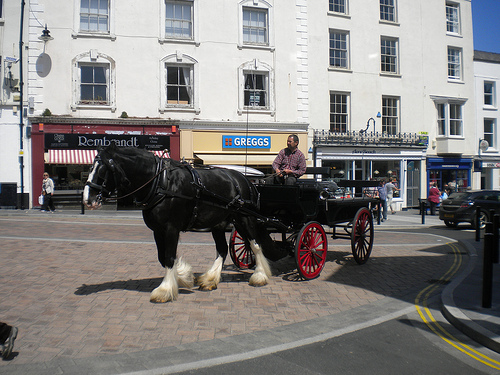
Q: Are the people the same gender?
A: No, they are both male and female.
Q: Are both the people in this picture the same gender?
A: No, they are both male and female.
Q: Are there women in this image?
A: Yes, there is a woman.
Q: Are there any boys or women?
A: Yes, there is a woman.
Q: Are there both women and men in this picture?
A: Yes, there are both a woman and a man.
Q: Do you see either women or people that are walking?
A: Yes, the woman is walking.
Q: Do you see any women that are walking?
A: Yes, there is a woman that is walking.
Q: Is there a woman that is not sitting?
A: Yes, there is a woman that is walking.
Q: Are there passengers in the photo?
A: No, there are no passengers.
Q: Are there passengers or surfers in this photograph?
A: No, there are no passengers or surfers.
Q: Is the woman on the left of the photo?
A: Yes, the woman is on the left of the image.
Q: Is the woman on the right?
A: No, the woman is on the left of the image.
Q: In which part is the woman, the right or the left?
A: The woman is on the left of the image.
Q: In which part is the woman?
A: The woman is on the left of the image.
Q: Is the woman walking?
A: Yes, the woman is walking.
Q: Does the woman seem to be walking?
A: Yes, the woman is walking.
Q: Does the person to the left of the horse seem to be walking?
A: Yes, the woman is walking.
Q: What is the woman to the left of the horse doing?
A: The woman is walking.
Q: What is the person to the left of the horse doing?
A: The woman is walking.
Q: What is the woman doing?
A: The woman is walking.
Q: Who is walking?
A: The woman is walking.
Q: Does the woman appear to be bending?
A: No, the woman is walking.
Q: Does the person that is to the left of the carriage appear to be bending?
A: No, the woman is walking.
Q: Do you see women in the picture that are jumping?
A: No, there is a woman but she is walking.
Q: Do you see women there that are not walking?
A: No, there is a woman but she is walking.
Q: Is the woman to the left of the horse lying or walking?
A: The woman is walking.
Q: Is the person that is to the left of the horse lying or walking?
A: The woman is walking.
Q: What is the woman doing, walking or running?
A: The woman is walking.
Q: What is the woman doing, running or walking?
A: The woman is walking.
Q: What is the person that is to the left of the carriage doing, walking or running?
A: The woman is walking.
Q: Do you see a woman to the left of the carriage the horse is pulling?
A: Yes, there is a woman to the left of the carriage.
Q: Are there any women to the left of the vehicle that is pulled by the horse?
A: Yes, there is a woman to the left of the carriage.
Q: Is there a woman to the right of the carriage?
A: No, the woman is to the left of the carriage.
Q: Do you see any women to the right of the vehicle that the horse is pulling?
A: No, the woman is to the left of the carriage.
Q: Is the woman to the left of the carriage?
A: Yes, the woman is to the left of the carriage.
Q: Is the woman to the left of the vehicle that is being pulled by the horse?
A: Yes, the woman is to the left of the carriage.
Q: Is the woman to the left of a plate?
A: No, the woman is to the left of the carriage.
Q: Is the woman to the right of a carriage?
A: No, the woman is to the left of a carriage.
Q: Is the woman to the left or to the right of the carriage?
A: The woman is to the left of the carriage.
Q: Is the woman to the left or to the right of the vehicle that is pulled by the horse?
A: The woman is to the left of the carriage.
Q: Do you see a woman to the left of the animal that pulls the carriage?
A: Yes, there is a woman to the left of the horse.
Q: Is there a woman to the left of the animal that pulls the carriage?
A: Yes, there is a woman to the left of the horse.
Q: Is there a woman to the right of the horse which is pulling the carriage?
A: No, the woman is to the left of the horse.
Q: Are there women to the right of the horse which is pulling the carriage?
A: No, the woman is to the left of the horse.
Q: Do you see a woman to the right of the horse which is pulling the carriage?
A: No, the woman is to the left of the horse.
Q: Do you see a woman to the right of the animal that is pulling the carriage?
A: No, the woman is to the left of the horse.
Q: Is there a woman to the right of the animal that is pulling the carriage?
A: No, the woman is to the left of the horse.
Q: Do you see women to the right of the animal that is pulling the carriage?
A: No, the woman is to the left of the horse.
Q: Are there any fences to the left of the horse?
A: No, there is a woman to the left of the horse.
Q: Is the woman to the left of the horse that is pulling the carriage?
A: Yes, the woman is to the left of the horse.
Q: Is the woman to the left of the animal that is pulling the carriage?
A: Yes, the woman is to the left of the horse.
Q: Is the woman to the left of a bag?
A: No, the woman is to the left of the horse.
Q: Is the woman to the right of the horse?
A: No, the woman is to the left of the horse.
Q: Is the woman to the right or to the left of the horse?
A: The woman is to the left of the horse.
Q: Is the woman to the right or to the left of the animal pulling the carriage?
A: The woman is to the left of the horse.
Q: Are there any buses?
A: No, there are no buses.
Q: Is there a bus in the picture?
A: No, there are no buses.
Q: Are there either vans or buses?
A: No, there are no buses or vans.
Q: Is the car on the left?
A: No, the car is on the right of the image.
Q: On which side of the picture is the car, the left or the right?
A: The car is on the right of the image.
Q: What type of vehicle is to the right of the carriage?
A: The vehicle is a car.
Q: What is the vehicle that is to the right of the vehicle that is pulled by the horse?
A: The vehicle is a car.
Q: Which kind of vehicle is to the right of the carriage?
A: The vehicle is a car.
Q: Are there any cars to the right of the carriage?
A: Yes, there is a car to the right of the carriage.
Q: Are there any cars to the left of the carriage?
A: No, the car is to the right of the carriage.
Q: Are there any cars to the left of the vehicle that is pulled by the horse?
A: No, the car is to the right of the carriage.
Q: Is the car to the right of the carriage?
A: Yes, the car is to the right of the carriage.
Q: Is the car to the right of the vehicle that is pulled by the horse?
A: Yes, the car is to the right of the carriage.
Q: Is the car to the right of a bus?
A: No, the car is to the right of the carriage.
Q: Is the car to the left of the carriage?
A: No, the car is to the right of the carriage.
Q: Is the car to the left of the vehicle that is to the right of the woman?
A: No, the car is to the right of the carriage.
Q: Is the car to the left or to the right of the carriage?
A: The car is to the right of the carriage.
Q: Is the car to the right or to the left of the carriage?
A: The car is to the right of the carriage.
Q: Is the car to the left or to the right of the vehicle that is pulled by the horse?
A: The car is to the right of the carriage.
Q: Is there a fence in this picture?
A: No, there are no fences.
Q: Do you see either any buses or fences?
A: No, there are no fences or buses.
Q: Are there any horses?
A: Yes, there is a horse.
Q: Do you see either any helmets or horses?
A: Yes, there is a horse.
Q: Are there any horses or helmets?
A: Yes, there is a horse.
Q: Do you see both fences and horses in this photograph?
A: No, there is a horse but no fences.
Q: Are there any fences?
A: No, there are no fences.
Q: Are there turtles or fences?
A: No, there are no fences or turtles.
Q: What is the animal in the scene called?
A: The animal is a horse.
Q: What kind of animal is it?
A: The animal is a horse.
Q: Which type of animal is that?
A: This is a horse.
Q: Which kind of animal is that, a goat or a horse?
A: This is a horse.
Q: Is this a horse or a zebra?
A: This is a horse.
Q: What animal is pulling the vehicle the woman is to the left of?
A: The horse is pulling the carriage.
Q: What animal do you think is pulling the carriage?
A: The animal is a horse.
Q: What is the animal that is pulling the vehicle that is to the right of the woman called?
A: The animal is a horse.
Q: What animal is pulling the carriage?
A: The animal is a horse.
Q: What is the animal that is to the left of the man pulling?
A: The horse is pulling the carriage.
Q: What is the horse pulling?
A: The horse is pulling the carriage.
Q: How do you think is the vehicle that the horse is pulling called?
A: The vehicle is a carriage.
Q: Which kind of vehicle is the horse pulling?
A: The horse is pulling the carriage.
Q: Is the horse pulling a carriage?
A: Yes, the horse is pulling a carriage.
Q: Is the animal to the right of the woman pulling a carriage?
A: Yes, the horse is pulling a carriage.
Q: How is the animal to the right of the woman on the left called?
A: The animal is a horse.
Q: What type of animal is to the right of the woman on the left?
A: The animal is a horse.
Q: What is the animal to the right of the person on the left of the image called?
A: The animal is a horse.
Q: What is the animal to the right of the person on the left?
A: The animal is a horse.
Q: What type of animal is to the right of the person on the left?
A: The animal is a horse.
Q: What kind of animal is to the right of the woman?
A: The animal is a horse.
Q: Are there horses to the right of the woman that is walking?
A: Yes, there is a horse to the right of the woman.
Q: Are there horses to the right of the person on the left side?
A: Yes, there is a horse to the right of the woman.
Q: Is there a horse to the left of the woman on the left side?
A: No, the horse is to the right of the woman.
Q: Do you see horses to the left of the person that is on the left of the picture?
A: No, the horse is to the right of the woman.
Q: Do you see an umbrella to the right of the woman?
A: No, there is a horse to the right of the woman.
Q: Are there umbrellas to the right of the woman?
A: No, there is a horse to the right of the woman.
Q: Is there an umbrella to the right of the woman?
A: No, there is a horse to the right of the woman.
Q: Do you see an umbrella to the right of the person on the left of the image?
A: No, there is a horse to the right of the woman.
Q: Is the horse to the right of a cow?
A: No, the horse is to the right of the woman.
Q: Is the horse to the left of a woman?
A: No, the horse is to the right of a woman.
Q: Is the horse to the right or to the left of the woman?
A: The horse is to the right of the woman.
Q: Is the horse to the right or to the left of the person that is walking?
A: The horse is to the right of the woman.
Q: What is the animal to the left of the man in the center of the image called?
A: The animal is a horse.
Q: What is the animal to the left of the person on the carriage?
A: The animal is a horse.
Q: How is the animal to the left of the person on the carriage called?
A: The animal is a horse.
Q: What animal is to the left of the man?
A: The animal is a horse.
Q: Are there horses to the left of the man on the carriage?
A: Yes, there is a horse to the left of the man.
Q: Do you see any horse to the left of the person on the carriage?
A: Yes, there is a horse to the left of the man.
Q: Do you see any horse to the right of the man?
A: No, the horse is to the left of the man.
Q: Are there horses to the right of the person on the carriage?
A: No, the horse is to the left of the man.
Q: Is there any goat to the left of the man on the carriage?
A: No, there is a horse to the left of the man.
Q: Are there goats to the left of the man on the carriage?
A: No, there is a horse to the left of the man.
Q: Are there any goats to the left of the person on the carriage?
A: No, there is a horse to the left of the man.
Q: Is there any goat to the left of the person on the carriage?
A: No, there is a horse to the left of the man.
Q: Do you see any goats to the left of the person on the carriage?
A: No, there is a horse to the left of the man.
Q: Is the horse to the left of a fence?
A: No, the horse is to the left of a man.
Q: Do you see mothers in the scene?
A: No, there are no mothers.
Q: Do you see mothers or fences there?
A: No, there are no mothers or fences.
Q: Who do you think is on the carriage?
A: The man is on the carriage.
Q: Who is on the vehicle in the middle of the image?
A: The man is on the carriage.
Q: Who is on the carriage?
A: The man is on the carriage.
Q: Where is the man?
A: The man is on the carriage.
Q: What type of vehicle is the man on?
A: The man is on the carriage.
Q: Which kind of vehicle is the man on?
A: The man is on the carriage.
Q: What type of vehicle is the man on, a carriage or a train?
A: The man is on a carriage.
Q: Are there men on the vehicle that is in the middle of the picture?
A: Yes, there is a man on the carriage.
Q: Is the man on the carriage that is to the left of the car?
A: Yes, the man is on the carriage.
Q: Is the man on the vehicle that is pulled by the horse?
A: Yes, the man is on the carriage.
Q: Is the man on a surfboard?
A: No, the man is on the carriage.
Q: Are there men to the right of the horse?
A: Yes, there is a man to the right of the horse.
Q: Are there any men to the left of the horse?
A: No, the man is to the right of the horse.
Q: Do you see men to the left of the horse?
A: No, the man is to the right of the horse.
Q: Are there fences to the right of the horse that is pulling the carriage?
A: No, there is a man to the right of the horse.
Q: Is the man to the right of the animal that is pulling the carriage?
A: Yes, the man is to the right of the horse.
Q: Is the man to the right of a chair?
A: No, the man is to the right of the horse.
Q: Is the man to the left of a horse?
A: No, the man is to the right of a horse.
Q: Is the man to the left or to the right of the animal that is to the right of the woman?
A: The man is to the right of the horse.